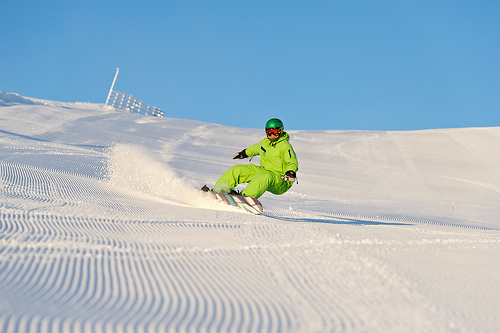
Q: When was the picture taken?
A: Daytime.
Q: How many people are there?
A: One.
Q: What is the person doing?
A: Snowboarding.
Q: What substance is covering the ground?
A: Snow.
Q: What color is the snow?
A: White.